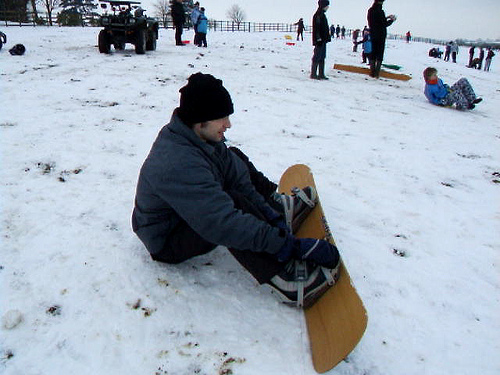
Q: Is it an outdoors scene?
A: Yes, it is outdoors.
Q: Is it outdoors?
A: Yes, it is outdoors.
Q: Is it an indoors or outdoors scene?
A: It is outdoors.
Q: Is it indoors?
A: No, it is outdoors.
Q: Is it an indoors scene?
A: No, it is outdoors.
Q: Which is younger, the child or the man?
A: The child is younger than the man.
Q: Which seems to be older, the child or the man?
A: The man is older than the child.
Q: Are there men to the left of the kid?
A: Yes, there is a man to the left of the kid.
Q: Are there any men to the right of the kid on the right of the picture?
A: No, the man is to the left of the child.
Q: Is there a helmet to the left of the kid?
A: No, there is a man to the left of the kid.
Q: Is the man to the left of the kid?
A: Yes, the man is to the left of the kid.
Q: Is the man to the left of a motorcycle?
A: No, the man is to the left of the kid.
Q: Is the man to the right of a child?
A: No, the man is to the left of a child.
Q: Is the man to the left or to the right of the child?
A: The man is to the left of the child.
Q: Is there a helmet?
A: No, there are no helmets.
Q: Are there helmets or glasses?
A: No, there are no helmets or glasses.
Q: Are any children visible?
A: Yes, there is a child.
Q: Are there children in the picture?
A: Yes, there is a child.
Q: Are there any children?
A: Yes, there is a child.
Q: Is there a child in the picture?
A: Yes, there is a child.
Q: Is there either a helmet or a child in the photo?
A: Yes, there is a child.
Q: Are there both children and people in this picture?
A: Yes, there are both a child and a person.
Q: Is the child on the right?
A: Yes, the child is on the right of the image.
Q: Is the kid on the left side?
A: No, the kid is on the right of the image.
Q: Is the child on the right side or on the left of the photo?
A: The child is on the right of the image.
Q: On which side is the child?
A: The child is on the right of the image.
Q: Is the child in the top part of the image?
A: Yes, the child is in the top of the image.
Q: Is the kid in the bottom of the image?
A: No, the kid is in the top of the image.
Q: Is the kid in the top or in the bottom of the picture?
A: The kid is in the top of the image.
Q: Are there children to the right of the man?
A: Yes, there is a child to the right of the man.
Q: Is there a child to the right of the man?
A: Yes, there is a child to the right of the man.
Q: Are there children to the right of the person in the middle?
A: Yes, there is a child to the right of the man.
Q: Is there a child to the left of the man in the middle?
A: No, the child is to the right of the man.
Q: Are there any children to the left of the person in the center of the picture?
A: No, the child is to the right of the man.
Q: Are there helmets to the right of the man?
A: No, there is a child to the right of the man.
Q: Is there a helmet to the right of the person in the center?
A: No, there is a child to the right of the man.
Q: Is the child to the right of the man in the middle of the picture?
A: Yes, the child is to the right of the man.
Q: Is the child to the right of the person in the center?
A: Yes, the child is to the right of the man.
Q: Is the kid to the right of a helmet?
A: No, the kid is to the right of the man.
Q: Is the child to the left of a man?
A: No, the child is to the right of a man.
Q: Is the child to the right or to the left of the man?
A: The child is to the right of the man.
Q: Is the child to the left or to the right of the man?
A: The child is to the right of the man.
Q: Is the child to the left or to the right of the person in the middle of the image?
A: The child is to the right of the man.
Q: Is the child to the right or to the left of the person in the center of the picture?
A: The child is to the right of the man.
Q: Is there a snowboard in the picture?
A: Yes, there is a snowboard.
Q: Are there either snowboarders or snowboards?
A: Yes, there is a snowboard.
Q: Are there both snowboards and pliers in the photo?
A: No, there is a snowboard but no pliers.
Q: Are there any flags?
A: No, there are no flags.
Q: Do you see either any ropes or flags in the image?
A: No, there are no flags or ropes.